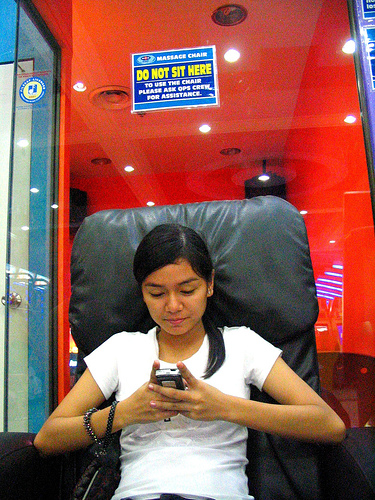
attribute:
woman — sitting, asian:
[29, 216, 368, 499]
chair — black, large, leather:
[0, 193, 373, 500]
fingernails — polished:
[144, 382, 161, 409]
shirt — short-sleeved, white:
[71, 323, 285, 500]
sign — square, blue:
[123, 42, 231, 121]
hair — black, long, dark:
[129, 216, 230, 382]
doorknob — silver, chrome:
[1, 290, 28, 315]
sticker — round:
[18, 75, 46, 107]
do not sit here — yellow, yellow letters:
[131, 60, 213, 85]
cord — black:
[82, 401, 120, 453]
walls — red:
[28, 0, 373, 353]